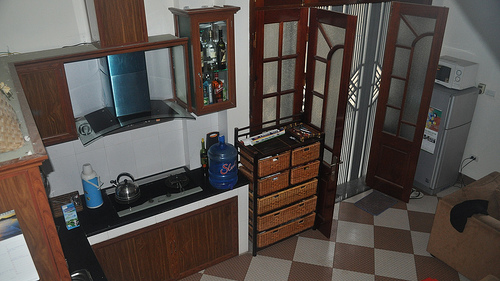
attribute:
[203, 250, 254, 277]
shape — brown, diamond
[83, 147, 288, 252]
cooktop — black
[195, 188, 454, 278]
tile floor — brown, white, checkered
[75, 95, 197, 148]
range hood — silver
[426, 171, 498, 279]
sofa chair — small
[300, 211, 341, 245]
shape — brown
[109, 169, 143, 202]
tea kettle — silver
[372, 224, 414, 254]
diamond shape — brown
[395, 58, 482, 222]
refrigerator — small, silver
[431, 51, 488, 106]
microwave — white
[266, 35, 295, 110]
window — small, frosted, glass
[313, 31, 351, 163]
window — small, frosted, glass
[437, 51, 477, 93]
microwave — white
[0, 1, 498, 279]
kitchen — interior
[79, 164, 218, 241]
back stove — black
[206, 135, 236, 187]
jug — blue, plastic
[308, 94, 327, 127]
window — small, frosted glass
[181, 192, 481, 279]
floor — tiled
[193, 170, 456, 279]
floor — brown, diamond patterned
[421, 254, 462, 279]
shape — diamond, brown